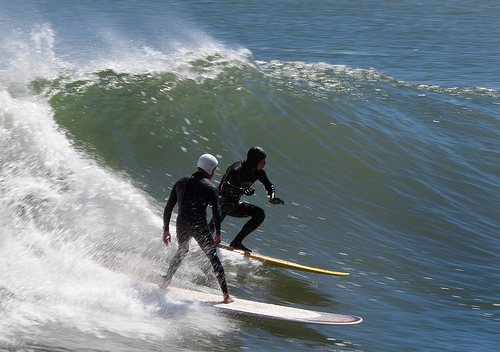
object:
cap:
[195, 154, 219, 176]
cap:
[244, 147, 266, 165]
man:
[157, 153, 234, 305]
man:
[206, 146, 285, 252]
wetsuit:
[158, 172, 230, 295]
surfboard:
[144, 283, 363, 326]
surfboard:
[211, 239, 352, 277]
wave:
[0, 0, 499, 351]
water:
[0, 0, 499, 351]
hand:
[267, 196, 285, 205]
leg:
[192, 232, 230, 298]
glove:
[267, 196, 287, 205]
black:
[161, 174, 230, 295]